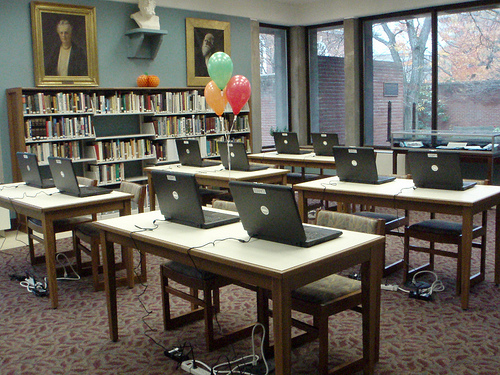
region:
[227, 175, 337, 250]
laptop on a desk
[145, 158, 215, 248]
laptop on a desk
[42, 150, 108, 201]
laptop on a desk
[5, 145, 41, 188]
lap top on a desk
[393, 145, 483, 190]
lap top on a desk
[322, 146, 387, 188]
lap top on a desk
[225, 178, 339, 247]
an open laptop computer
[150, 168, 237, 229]
an open laptop computer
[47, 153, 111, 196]
an open laptop computer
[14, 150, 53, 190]
an open laptop computer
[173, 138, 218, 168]
an open laptop computer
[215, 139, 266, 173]
an open laptop computer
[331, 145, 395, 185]
an open laptop computer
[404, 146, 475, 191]
an open laptop computer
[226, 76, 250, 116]
a red helium filled balloon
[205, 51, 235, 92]
a green helium filled balloon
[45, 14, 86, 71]
Person in a portrait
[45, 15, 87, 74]
Lady in a portrait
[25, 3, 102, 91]
Frame around a portrait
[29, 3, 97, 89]
Gold frame around a picture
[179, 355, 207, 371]
Power outlet on the floor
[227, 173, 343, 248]
Laptop is open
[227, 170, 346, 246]
Black laptop is open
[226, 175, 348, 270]
Laptop on a table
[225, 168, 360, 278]
Black laptop on a table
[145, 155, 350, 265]
Two laptops on a table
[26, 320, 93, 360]
pattern carpet on floor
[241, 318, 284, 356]
white electrical cord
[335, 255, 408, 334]
wooden legs on table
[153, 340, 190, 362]
black electrical port on floor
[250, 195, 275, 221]
white circular logo on back of lap top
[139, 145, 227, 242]
black lap top on table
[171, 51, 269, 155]
cluster of colorful balloons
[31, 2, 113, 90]
large picture on wall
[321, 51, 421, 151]
red bricks on wall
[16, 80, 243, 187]
many books in book shelf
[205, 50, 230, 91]
The green floating balloon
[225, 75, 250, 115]
The red balloon in the group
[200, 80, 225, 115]
The orange balloon in the group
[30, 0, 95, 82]
The left picture on the wall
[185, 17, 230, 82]
The right picture on the wall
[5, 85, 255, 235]
The bookshelf against the wall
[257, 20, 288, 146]
The left window on the wall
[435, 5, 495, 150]
The rightmost window on the wall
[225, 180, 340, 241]
The closest laptop on the desk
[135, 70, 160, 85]
The orange decoration on the bookshelf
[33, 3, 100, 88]
Picture of an elderly lady in a gold frame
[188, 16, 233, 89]
Picture of an elderly man in a gold frame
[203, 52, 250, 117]
Red, green, and orange balloons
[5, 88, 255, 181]
A large shelf of books